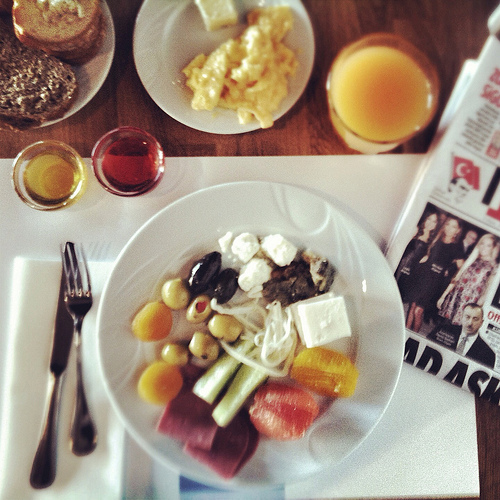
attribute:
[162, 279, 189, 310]
olive — green, palmetto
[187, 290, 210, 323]
olive — green, palmetto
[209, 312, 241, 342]
olive — green, palmetto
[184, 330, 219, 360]
olive — green, palmetto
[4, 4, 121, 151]
toast — different kinds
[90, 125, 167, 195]
cup — small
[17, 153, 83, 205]
liquid — yellow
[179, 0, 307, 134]
eggs — scrambled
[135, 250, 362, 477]
fruit — cut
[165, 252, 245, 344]
olives — green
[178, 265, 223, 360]
olives — different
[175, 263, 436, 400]
feta cheese — white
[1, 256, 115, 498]
napkin — white, paper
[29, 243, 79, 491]
knife — silver